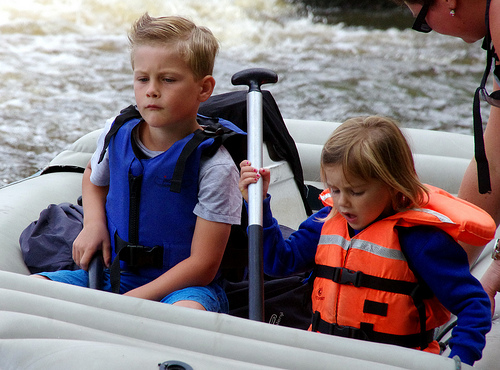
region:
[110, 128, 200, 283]
a blue life jacket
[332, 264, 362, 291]
the palstic black clip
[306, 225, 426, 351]
the orange life vest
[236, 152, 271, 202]
the hand holds the ore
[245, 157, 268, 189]
the pink fingernails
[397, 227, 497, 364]
the blue sweater sleeve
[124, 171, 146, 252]
zipper on the life jacket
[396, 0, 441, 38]
glasses on her face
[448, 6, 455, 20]
earings in the womens ear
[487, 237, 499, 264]
the face of the wristwatch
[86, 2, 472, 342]
A boy and a girl sitting in the raft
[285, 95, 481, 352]
A girl wearing orange floater vest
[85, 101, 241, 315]
A boy wearing blue floater vest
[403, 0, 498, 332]
An adult supervising the kids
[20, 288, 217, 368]
Light grey inflatable raft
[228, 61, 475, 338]
A girl holding a silver and black rod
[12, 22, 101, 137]
Turbulent water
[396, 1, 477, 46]
A woman wearing black sunglasses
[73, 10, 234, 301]
A boy wearing grey shirt and blue shorts underneath the lifejacket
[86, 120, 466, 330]
Blue and orange lifejackets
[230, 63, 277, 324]
Silver, gray and black handle and pole on a paddle.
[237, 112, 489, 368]
Little girl holding a pole and wearing an almost all orange life vest.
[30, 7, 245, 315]
Little blonde haired boy wearing a blue life jacket.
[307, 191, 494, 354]
Orange, black and silver life vest on a girl.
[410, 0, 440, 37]
Black sunglasses on a woman's face.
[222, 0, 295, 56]
Many white splashes and waves behind a boys head.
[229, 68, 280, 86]
Black handle at the end of a paddle.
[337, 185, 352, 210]
Small nose on a girl's face.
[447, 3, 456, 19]
Small earring in a woman's ear.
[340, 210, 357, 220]
Open mouth of a little light haired girl.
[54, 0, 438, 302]
two young children in a water raft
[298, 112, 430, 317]
a young girl wearing a orange life jacket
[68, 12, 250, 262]
a young boy wearing a blue life jacket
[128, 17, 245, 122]
a young boy with blonde hair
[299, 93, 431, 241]
a young girl with blonde hair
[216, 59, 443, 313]
a young girl holding a oar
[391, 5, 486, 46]
a woman wearing sun glasses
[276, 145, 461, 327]
a young girl wearing a blue shirt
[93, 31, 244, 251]
a young boy wearing a grey shirt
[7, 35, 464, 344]
two children wearing life jackets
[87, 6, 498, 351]
a boy and girl in a raft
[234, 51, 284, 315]
a silver and black paddle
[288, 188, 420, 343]
an orange life jacket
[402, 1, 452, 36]
thick black sunglasses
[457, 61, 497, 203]
a black strape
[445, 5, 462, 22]
an ear with earrings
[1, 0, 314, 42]
rapids on a river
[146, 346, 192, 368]
a black air plug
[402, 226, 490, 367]
a crinkled blue sleeve